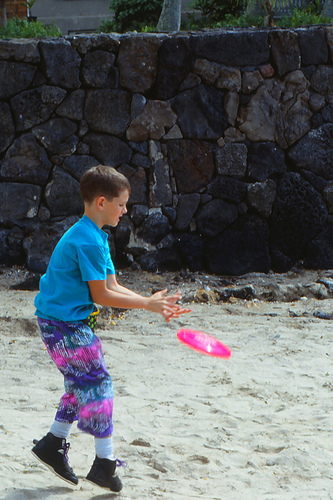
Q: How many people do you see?
A: 1.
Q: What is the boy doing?
A: Playing frisbee.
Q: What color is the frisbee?
A: Pink.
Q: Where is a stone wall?
A: Behind the boy.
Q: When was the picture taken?
A: During daylight.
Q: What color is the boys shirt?
A: Blue.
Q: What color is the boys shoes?
A: Black.